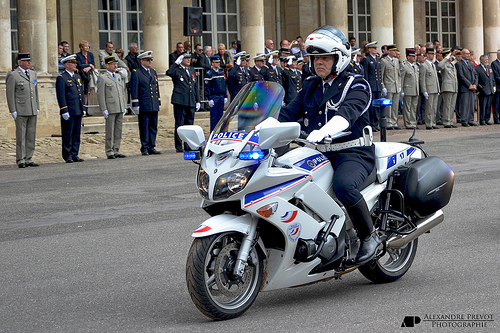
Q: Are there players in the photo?
A: No, there are no players.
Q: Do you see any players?
A: No, there are no players.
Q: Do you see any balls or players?
A: No, there are no players or balls.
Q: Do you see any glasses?
A: No, there are no glasses.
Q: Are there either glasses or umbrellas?
A: No, there are no glasses or umbrellas.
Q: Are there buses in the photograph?
A: No, there are no buses.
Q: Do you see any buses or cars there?
A: No, there are no buses or cars.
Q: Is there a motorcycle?
A: Yes, there is a motorcycle.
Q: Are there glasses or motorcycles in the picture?
A: Yes, there is a motorcycle.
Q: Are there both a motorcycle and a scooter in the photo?
A: No, there is a motorcycle but no scooters.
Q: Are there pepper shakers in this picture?
A: No, there are no pepper shakers.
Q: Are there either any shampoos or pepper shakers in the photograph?
A: No, there are no pepper shakers or shampoos.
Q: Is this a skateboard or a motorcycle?
A: This is a motorcycle.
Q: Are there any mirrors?
A: Yes, there is a mirror.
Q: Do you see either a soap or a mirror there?
A: Yes, there is a mirror.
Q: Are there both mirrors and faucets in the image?
A: No, there is a mirror but no faucets.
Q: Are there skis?
A: No, there are no skis.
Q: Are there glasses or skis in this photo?
A: No, there are no skis or glasses.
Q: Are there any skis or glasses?
A: No, there are no skis or glasses.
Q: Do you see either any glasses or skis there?
A: No, there are no skis or glasses.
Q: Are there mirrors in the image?
A: Yes, there is a mirror.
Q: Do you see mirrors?
A: Yes, there is a mirror.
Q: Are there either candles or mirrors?
A: Yes, there is a mirror.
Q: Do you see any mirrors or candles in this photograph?
A: Yes, there is a mirror.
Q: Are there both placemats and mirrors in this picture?
A: No, there is a mirror but no placemats.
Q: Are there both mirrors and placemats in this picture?
A: No, there is a mirror but no placemats.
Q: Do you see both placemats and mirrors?
A: No, there is a mirror but no placemats.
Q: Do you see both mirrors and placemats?
A: No, there is a mirror but no placemats.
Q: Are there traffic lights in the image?
A: No, there are no traffic lights.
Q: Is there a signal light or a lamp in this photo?
A: No, there are no traffic lights or lamps.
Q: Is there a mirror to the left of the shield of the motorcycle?
A: Yes, there is a mirror to the left of the shield.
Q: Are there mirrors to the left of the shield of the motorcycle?
A: Yes, there is a mirror to the left of the shield.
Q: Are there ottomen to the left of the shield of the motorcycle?
A: No, there is a mirror to the left of the shield.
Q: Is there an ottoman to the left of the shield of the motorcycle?
A: No, there is a mirror to the left of the shield.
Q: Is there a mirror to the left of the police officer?
A: Yes, there is a mirror to the left of the police officer.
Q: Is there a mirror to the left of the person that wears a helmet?
A: Yes, there is a mirror to the left of the police officer.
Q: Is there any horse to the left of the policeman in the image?
A: No, there is a mirror to the left of the policeman.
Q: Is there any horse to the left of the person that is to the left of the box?
A: No, there is a mirror to the left of the policeman.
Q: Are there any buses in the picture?
A: No, there are no buses.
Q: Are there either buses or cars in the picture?
A: No, there are no buses or cars.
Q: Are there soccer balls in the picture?
A: No, there are no soccer balls.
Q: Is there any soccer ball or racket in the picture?
A: No, there are no soccer balls or rackets.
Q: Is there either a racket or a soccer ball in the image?
A: No, there are no soccer balls or rackets.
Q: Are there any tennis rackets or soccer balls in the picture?
A: No, there are no soccer balls or tennis rackets.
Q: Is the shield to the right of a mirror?
A: Yes, the shield is to the right of a mirror.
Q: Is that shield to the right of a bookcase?
A: No, the shield is to the right of a mirror.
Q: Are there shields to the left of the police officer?
A: Yes, there is a shield to the left of the police officer.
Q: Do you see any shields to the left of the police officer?
A: Yes, there is a shield to the left of the police officer.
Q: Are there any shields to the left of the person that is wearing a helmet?
A: Yes, there is a shield to the left of the police officer.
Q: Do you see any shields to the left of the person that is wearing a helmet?
A: Yes, there is a shield to the left of the police officer.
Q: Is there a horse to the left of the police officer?
A: No, there is a shield to the left of the police officer.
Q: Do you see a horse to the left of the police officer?
A: No, there is a shield to the left of the police officer.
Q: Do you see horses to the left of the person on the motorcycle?
A: No, there is a shield to the left of the police officer.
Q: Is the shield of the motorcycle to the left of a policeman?
A: Yes, the shield is to the left of a policeman.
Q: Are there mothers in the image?
A: No, there are no mothers.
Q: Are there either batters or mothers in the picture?
A: No, there are no mothers or batters.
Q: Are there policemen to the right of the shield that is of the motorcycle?
A: Yes, there is a policeman to the right of the shield.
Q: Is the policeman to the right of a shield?
A: Yes, the policeman is to the right of a shield.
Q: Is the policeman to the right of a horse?
A: No, the policeman is to the right of a shield.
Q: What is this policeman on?
A: The policeman is on the motorbike.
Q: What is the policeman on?
A: The policeman is on the motorbike.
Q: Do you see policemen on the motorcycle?
A: Yes, there is a policeman on the motorcycle.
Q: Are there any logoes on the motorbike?
A: No, there is a policeman on the motorbike.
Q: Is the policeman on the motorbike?
A: Yes, the policeman is on the motorbike.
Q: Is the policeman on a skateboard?
A: No, the policeman is on the motorbike.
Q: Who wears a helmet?
A: The police officer wears a helmet.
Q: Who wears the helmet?
A: The police officer wears a helmet.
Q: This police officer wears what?
A: The police officer wears a helmet.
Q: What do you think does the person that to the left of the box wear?
A: The police officer wears a helmet.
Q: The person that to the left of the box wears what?
A: The police officer wears a helmet.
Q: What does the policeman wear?
A: The police officer wears a helmet.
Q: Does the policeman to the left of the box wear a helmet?
A: Yes, the policeman wears a helmet.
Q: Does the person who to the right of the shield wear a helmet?
A: Yes, the policeman wears a helmet.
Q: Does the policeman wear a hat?
A: No, the policeman wears a helmet.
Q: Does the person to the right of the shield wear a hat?
A: No, the policeman wears a helmet.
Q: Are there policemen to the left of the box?
A: Yes, there is a policeman to the left of the box.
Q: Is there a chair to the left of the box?
A: No, there is a policeman to the left of the box.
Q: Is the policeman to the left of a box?
A: Yes, the policeman is to the left of a box.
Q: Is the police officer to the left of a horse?
A: No, the police officer is to the left of a box.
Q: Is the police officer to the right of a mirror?
A: Yes, the police officer is to the right of a mirror.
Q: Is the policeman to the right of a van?
A: No, the policeman is to the right of a mirror.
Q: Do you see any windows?
A: Yes, there is a window.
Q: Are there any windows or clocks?
A: Yes, there is a window.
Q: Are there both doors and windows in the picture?
A: No, there is a window but no doors.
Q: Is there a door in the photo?
A: No, there are no doors.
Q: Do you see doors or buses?
A: No, there are no doors or buses.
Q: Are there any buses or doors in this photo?
A: No, there are no doors or buses.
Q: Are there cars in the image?
A: No, there are no cars.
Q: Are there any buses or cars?
A: No, there are no cars or buses.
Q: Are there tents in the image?
A: No, there are no tents.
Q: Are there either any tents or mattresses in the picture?
A: No, there are no tents or mattresses.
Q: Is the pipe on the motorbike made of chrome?
A: Yes, the pipe is made of chrome.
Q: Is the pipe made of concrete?
A: No, the pipe is made of chrome.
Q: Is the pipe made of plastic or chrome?
A: The pipe is made of chrome.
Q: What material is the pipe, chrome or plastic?
A: The pipe is made of chrome.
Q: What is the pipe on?
A: The pipe is on the motorbike.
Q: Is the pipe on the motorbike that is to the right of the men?
A: Yes, the pipe is on the motorbike.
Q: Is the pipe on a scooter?
A: No, the pipe is on the motorbike.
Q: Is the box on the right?
A: Yes, the box is on the right of the image.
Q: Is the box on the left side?
A: No, the box is on the right of the image.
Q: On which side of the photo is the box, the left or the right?
A: The box is on the right of the image.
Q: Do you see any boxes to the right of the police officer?
A: Yes, there is a box to the right of the police officer.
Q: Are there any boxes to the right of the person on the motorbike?
A: Yes, there is a box to the right of the police officer.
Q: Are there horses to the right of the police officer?
A: No, there is a box to the right of the police officer.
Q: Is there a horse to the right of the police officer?
A: No, there is a box to the right of the police officer.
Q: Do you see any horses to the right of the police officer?
A: No, there is a box to the right of the police officer.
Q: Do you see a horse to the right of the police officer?
A: No, there is a box to the right of the police officer.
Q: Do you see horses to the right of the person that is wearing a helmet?
A: No, there is a box to the right of the police officer.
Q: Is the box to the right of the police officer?
A: Yes, the box is to the right of the police officer.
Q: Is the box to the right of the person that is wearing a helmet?
A: Yes, the box is to the right of the police officer.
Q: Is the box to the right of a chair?
A: No, the box is to the right of the police officer.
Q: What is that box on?
A: The box is on the motorbike.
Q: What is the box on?
A: The box is on the motorbike.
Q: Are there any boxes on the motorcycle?
A: Yes, there is a box on the motorcycle.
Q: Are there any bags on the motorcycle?
A: No, there is a box on the motorcycle.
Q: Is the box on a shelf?
A: No, the box is on the motorbike.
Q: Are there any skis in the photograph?
A: No, there are no skis.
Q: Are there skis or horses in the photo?
A: No, there are no skis or horses.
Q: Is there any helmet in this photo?
A: Yes, there is a helmet.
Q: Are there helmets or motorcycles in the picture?
A: Yes, there is a helmet.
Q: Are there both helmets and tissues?
A: No, there is a helmet but no tissues.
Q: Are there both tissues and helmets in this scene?
A: No, there is a helmet but no tissues.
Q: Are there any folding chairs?
A: No, there are no folding chairs.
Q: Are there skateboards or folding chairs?
A: No, there are no folding chairs or skateboards.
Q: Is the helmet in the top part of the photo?
A: Yes, the helmet is in the top of the image.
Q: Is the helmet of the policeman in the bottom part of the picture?
A: No, the helmet is in the top of the image.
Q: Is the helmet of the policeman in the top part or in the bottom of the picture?
A: The helmet is in the top of the image.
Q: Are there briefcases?
A: No, there are no briefcases.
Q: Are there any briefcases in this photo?
A: No, there are no briefcases.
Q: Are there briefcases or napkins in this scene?
A: No, there are no briefcases or napkins.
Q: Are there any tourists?
A: No, there are no tourists.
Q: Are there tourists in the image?
A: No, there are no tourists.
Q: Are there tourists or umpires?
A: No, there are no tourists or umpires.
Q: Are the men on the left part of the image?
A: Yes, the men are on the left of the image.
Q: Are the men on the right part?
A: No, the men are on the left of the image.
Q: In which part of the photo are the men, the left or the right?
A: The men are on the left of the image.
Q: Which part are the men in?
A: The men are on the left of the image.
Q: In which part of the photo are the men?
A: The men are on the left of the image.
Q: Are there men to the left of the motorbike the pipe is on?
A: Yes, there are men to the left of the motorcycle.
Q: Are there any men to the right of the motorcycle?
A: No, the men are to the left of the motorcycle.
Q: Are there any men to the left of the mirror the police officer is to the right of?
A: Yes, there are men to the left of the mirror.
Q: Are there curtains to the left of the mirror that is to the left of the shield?
A: No, there are men to the left of the mirror.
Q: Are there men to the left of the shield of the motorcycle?
A: Yes, there are men to the left of the shield.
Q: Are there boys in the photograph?
A: No, there are no boys.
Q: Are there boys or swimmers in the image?
A: No, there are no boys or swimmers.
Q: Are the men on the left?
A: Yes, the men are on the left of the image.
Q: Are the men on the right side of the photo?
A: No, the men are on the left of the image.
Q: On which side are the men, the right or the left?
A: The men are on the left of the image.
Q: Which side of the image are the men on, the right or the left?
A: The men are on the left of the image.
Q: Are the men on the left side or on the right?
A: The men are on the left of the image.